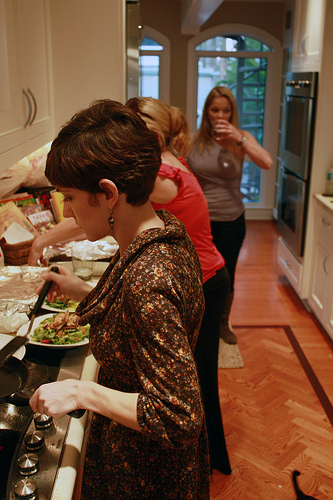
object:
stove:
[0, 348, 85, 500]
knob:
[11, 478, 39, 497]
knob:
[24, 432, 45, 453]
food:
[50, 311, 69, 329]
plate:
[26, 314, 90, 349]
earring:
[108, 210, 116, 236]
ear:
[99, 177, 119, 211]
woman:
[188, 85, 273, 345]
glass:
[213, 121, 225, 141]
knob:
[305, 81, 310, 85]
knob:
[33, 412, 55, 428]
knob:
[15, 454, 38, 477]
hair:
[45, 98, 165, 205]